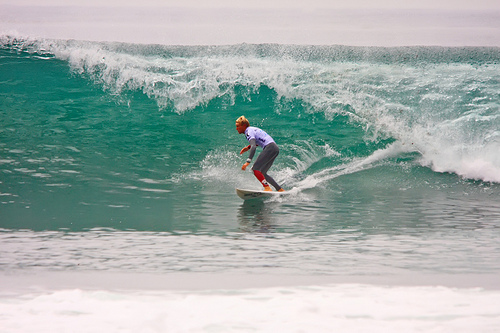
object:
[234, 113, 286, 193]
man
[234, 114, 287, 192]
girl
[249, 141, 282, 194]
pants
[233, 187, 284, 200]
board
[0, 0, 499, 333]
sunshine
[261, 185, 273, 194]
feet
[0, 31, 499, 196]
bubbles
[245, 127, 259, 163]
arms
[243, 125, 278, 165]
shirt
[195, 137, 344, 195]
wave mist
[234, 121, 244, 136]
face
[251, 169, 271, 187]
cord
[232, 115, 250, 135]
head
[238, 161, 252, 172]
hands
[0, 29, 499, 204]
gaint wave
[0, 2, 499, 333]
ocean